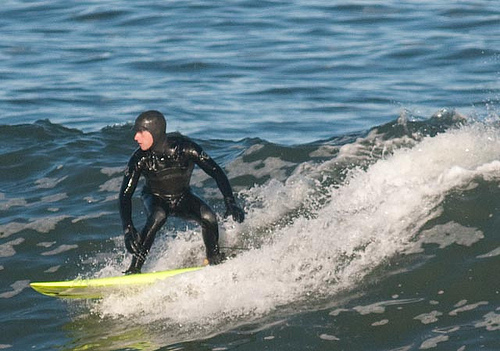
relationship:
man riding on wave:
[115, 110, 245, 275] [1, 109, 498, 329]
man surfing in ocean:
[115, 110, 245, 275] [1, 0, 498, 351]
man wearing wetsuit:
[115, 110, 245, 275] [118, 109, 245, 275]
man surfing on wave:
[115, 110, 245, 275] [1, 109, 498, 329]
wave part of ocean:
[1, 109, 498, 329] [1, 0, 498, 351]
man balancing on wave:
[115, 110, 245, 275] [1, 109, 498, 329]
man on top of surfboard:
[115, 110, 245, 275] [28, 261, 247, 301]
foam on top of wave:
[1, 113, 498, 350] [1, 109, 498, 329]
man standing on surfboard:
[115, 110, 245, 275] [28, 261, 247, 301]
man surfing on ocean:
[115, 110, 245, 275] [1, 0, 498, 351]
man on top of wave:
[115, 110, 245, 275] [1, 109, 498, 329]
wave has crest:
[1, 109, 498, 329] [1, 105, 499, 153]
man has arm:
[115, 110, 245, 275] [178, 134, 246, 225]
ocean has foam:
[1, 0, 498, 351] [1, 113, 498, 350]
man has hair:
[115, 110, 245, 275] [130, 124, 146, 132]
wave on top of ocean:
[1, 109, 498, 329] [1, 0, 498, 351]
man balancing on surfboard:
[115, 110, 245, 275] [28, 261, 247, 301]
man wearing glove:
[115, 110, 245, 275] [222, 195, 245, 222]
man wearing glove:
[115, 110, 245, 275] [121, 221, 144, 256]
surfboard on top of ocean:
[28, 261, 247, 301] [1, 0, 498, 351]